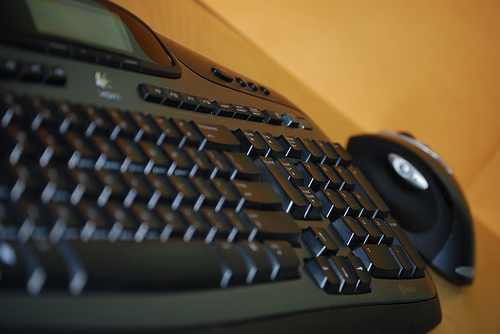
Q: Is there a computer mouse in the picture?
A: Yes, there is a computer mouse.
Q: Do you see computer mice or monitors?
A: Yes, there is a computer mouse.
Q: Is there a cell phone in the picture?
A: No, there are no cell phones.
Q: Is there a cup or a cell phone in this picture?
A: No, there are no cell phones or cups.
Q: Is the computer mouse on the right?
A: Yes, the computer mouse is on the right of the image.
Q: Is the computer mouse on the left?
A: No, the computer mouse is on the right of the image.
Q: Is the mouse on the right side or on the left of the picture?
A: The mouse is on the right of the image.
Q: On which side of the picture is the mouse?
A: The mouse is on the right of the image.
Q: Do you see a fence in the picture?
A: No, there are no fences.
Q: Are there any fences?
A: No, there are no fences.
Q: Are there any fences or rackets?
A: No, there are no fences or rackets.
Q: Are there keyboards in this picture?
A: Yes, there is a keyboard.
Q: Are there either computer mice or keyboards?
A: Yes, there is a keyboard.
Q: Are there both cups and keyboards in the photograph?
A: No, there is a keyboard but no cups.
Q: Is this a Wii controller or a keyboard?
A: This is a keyboard.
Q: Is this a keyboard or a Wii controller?
A: This is a keyboard.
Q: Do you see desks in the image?
A: Yes, there is a desk.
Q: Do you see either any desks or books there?
A: Yes, there is a desk.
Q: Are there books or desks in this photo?
A: Yes, there is a desk.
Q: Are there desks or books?
A: Yes, there is a desk.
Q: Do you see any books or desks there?
A: Yes, there is a desk.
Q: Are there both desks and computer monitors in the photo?
A: No, there is a desk but no computer monitors.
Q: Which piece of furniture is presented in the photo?
A: The piece of furniture is a desk.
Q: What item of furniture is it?
A: The piece of furniture is a desk.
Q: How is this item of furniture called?
A: This is a desk.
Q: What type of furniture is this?
A: This is a desk.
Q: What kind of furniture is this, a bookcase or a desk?
A: This is a desk.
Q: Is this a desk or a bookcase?
A: This is a desk.